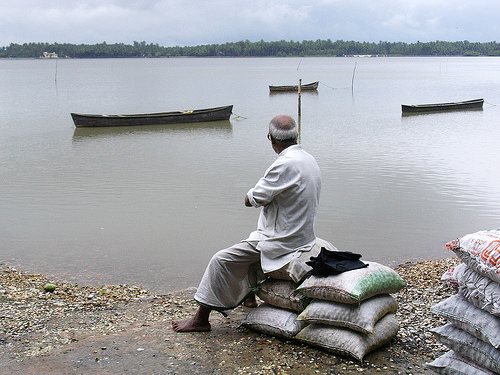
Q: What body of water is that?
A: A lake.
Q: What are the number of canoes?
A: Three.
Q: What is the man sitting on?
A: Packages.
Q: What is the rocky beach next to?
A: Water.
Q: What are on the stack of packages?
A: Red writing.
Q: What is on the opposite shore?
A: Green foliage.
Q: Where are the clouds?
A: In the sky.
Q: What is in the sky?
A: Clouds.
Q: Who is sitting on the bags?
A: The man.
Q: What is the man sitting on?
A: The bags.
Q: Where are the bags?
A: On the shore.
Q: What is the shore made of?
A: Mud and rocks.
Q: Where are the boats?
A: In the water.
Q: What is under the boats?
A: Water.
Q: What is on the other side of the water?
A: A row of trees.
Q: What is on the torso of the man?
A: A white shirt.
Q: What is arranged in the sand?
A: White sacks.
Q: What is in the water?
A: Three boats.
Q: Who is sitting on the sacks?
A: One man.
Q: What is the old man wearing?
A: White dress.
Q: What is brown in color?
A: Water.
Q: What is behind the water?
A: Trees.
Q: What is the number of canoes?
A: Three.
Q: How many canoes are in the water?
A: Three.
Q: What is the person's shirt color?
A: White.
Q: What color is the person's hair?
A: White.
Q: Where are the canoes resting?
A: In the water.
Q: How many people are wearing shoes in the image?
A: Zero.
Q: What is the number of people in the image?
A: One.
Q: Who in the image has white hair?
A: The person.